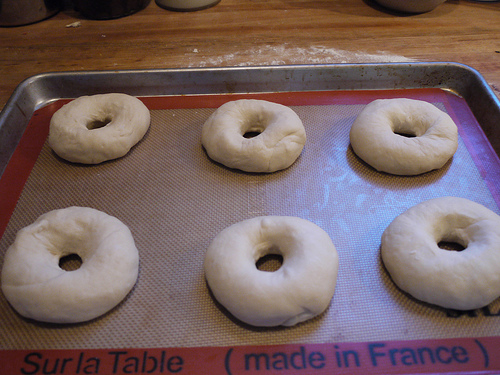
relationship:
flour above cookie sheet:
[186, 43, 418, 68] [0, 62, 500, 372]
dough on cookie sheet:
[2, 205, 139, 324] [0, 62, 500, 372]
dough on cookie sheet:
[49, 94, 150, 165] [0, 62, 500, 372]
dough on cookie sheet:
[204, 216, 338, 325] [0, 62, 500, 372]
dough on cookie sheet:
[203, 100, 308, 174] [0, 62, 500, 372]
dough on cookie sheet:
[351, 98, 458, 175] [0, 62, 500, 372]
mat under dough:
[0, 90, 499, 374] [49, 94, 150, 165]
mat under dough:
[0, 90, 499, 374] [203, 100, 308, 174]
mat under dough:
[0, 90, 499, 374] [351, 98, 458, 175]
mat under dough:
[0, 90, 499, 374] [2, 205, 139, 324]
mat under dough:
[0, 90, 499, 374] [204, 216, 338, 325]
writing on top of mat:
[22, 339, 490, 374] [0, 90, 499, 374]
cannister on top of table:
[0, 1, 223, 27] [0, 1, 500, 115]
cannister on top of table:
[364, 2, 444, 14] [0, 1, 500, 115]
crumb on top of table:
[65, 20, 83, 29] [0, 1, 500, 115]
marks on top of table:
[495, 49, 500, 54] [0, 1, 500, 115]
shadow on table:
[285, 2, 459, 18] [0, 1, 500, 115]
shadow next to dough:
[179, 119, 284, 182] [203, 100, 308, 174]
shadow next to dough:
[347, 141, 455, 189] [351, 98, 458, 175]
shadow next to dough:
[378, 241, 470, 318] [380, 198, 499, 312]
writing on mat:
[22, 339, 490, 374] [0, 90, 499, 374]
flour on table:
[186, 43, 418, 68] [0, 1, 500, 115]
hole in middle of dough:
[87, 115, 112, 131] [49, 94, 150, 165]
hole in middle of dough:
[244, 126, 263, 138] [203, 100, 308, 174]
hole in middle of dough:
[393, 127, 419, 139] [351, 98, 458, 175]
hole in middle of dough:
[58, 251, 83, 272] [2, 205, 139, 324]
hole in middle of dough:
[256, 251, 284, 272] [204, 216, 338, 325]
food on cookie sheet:
[0, 90, 499, 374] [0, 62, 500, 372]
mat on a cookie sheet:
[0, 90, 499, 374] [0, 62, 500, 372]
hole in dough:
[87, 115, 112, 131] [49, 94, 150, 165]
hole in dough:
[244, 126, 263, 138] [203, 100, 308, 174]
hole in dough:
[393, 127, 419, 139] [351, 98, 458, 175]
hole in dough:
[58, 251, 83, 272] [2, 205, 139, 324]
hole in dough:
[256, 251, 284, 272] [204, 216, 338, 325]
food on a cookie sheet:
[5, 93, 499, 326] [0, 62, 500, 372]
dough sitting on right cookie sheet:
[380, 198, 499, 312] [0, 62, 500, 372]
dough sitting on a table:
[5, 93, 499, 326] [0, 1, 500, 115]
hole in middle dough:
[256, 251, 284, 272] [204, 216, 338, 325]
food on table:
[5, 93, 499, 326] [0, 1, 500, 115]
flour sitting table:
[186, 43, 418, 68] [0, 1, 500, 115]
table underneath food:
[0, 1, 500, 115] [5, 93, 499, 326]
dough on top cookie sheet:
[203, 100, 308, 174] [0, 62, 500, 372]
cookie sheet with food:
[0, 62, 500, 372] [5, 93, 499, 326]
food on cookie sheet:
[5, 93, 499, 326] [0, 62, 500, 372]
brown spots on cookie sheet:
[385, 66, 471, 92] [0, 62, 500, 372]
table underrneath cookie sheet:
[0, 1, 500, 115] [0, 62, 500, 372]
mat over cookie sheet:
[0, 90, 499, 374] [0, 62, 500, 372]